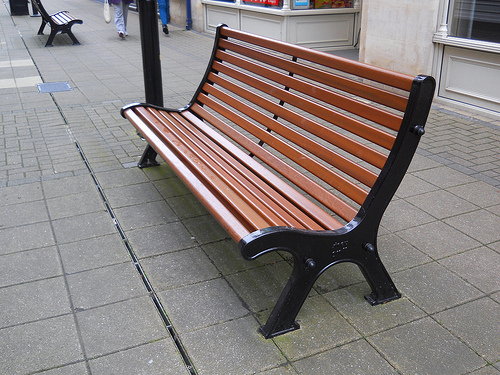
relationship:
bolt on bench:
[302, 239, 327, 274] [114, 19, 462, 300]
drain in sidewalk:
[24, 62, 89, 106] [28, 22, 242, 237]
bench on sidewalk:
[114, 19, 462, 300] [28, 22, 242, 237]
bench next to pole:
[114, 19, 462, 300] [106, 5, 176, 141]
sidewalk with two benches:
[4, 217, 486, 361] [11, 182, 487, 340]